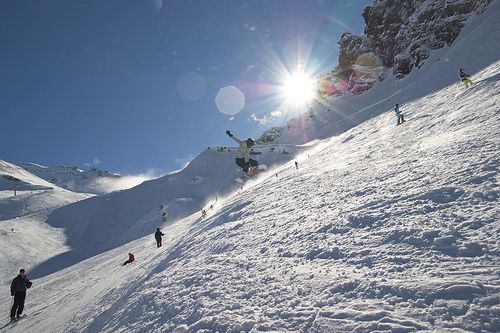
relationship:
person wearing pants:
[458, 68, 477, 92] [462, 79, 473, 90]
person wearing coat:
[392, 103, 407, 126] [394, 108, 404, 117]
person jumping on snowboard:
[224, 129, 268, 187] [235, 162, 267, 187]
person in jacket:
[120, 250, 136, 268] [128, 252, 137, 263]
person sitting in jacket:
[120, 250, 136, 268] [128, 252, 137, 263]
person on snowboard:
[224, 129, 268, 187] [235, 162, 267, 187]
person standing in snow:
[152, 227, 167, 248] [0, 158, 498, 332]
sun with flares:
[251, 44, 341, 129] [257, 37, 323, 69]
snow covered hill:
[0, 158, 498, 332] [0, 158, 99, 224]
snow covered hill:
[0, 158, 498, 332] [30, 162, 145, 197]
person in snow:
[458, 68, 477, 92] [0, 158, 498, 332]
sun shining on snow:
[251, 44, 341, 129] [0, 158, 498, 332]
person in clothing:
[152, 227, 167, 248] [153, 231, 165, 249]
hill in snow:
[0, 158, 99, 224] [0, 158, 498, 332]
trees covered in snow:
[318, 2, 492, 99] [402, 9, 421, 22]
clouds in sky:
[84, 154, 106, 169] [1, 1, 376, 177]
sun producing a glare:
[251, 44, 341, 129] [174, 68, 255, 124]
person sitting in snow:
[120, 250, 136, 268] [0, 158, 498, 332]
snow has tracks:
[0, 158, 498, 332] [268, 186, 499, 332]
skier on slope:
[1, 266, 37, 331] [3, 207, 256, 331]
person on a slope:
[458, 68, 477, 92] [3, 207, 256, 331]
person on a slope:
[152, 227, 167, 248] [3, 207, 256, 331]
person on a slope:
[392, 103, 407, 126] [3, 207, 256, 331]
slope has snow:
[3, 207, 256, 331] [0, 158, 498, 332]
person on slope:
[458, 68, 477, 92] [3, 207, 256, 331]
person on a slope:
[120, 250, 136, 268] [3, 207, 256, 331]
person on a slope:
[224, 129, 268, 187] [3, 207, 256, 331]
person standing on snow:
[152, 227, 167, 248] [0, 158, 498, 332]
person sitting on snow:
[120, 250, 136, 268] [0, 158, 498, 332]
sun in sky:
[251, 44, 341, 129] [1, 1, 376, 177]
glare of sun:
[174, 68, 255, 124] [251, 44, 341, 129]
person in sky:
[224, 129, 268, 187] [1, 1, 376, 177]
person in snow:
[392, 103, 407, 126] [0, 158, 498, 332]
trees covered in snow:
[318, 2, 492, 99] [0, 158, 498, 332]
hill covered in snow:
[0, 158, 99, 224] [0, 158, 498, 332]